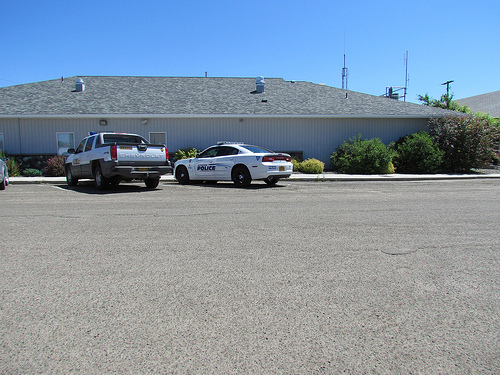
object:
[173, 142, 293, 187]
car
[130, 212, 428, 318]
lot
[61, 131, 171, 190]
truck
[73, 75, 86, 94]
vent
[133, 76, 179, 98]
roof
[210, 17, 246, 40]
sky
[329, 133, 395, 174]
bushes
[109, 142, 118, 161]
lights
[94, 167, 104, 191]
wheel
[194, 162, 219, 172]
logo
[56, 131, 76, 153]
window